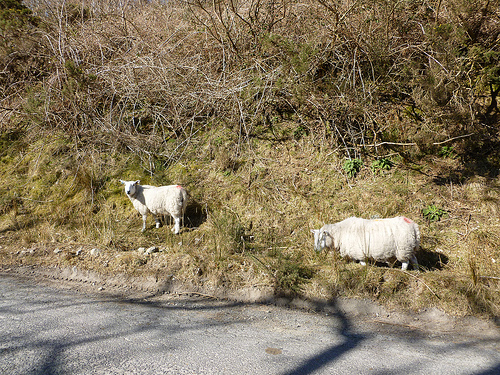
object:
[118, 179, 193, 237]
sheep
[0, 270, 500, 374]
road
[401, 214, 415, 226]
mark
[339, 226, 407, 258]
fur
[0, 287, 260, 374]
shadows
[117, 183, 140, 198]
face